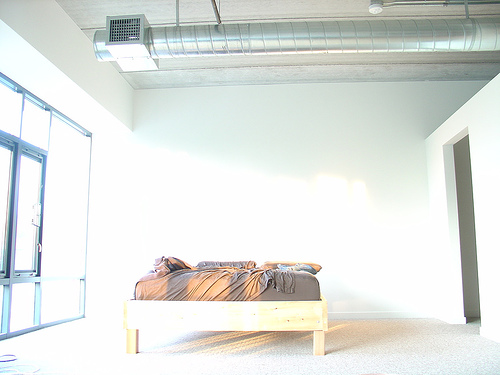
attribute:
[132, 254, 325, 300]
bed — double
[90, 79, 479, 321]
wall — white color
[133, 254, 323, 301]
blanket — brown, orange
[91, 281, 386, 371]
frame — wooden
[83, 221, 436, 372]
bed — platform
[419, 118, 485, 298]
doorway — leading out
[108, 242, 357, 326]
sheets — orange, brown, bed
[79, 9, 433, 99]
vent — air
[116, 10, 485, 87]
pipe — metal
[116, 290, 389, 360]
bedframe — light, wood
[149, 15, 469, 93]
ducting — ventilation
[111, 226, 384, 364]
frame — pine, bed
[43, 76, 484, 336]
room — middle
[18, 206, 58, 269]
latch — lock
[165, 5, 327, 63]
strapping — metal